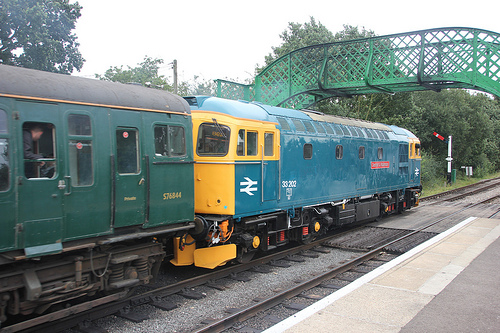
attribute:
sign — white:
[428, 130, 449, 144]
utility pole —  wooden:
[162, 52, 189, 94]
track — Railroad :
[5, 184, 499, 329]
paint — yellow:
[209, 163, 231, 200]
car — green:
[5, 65, 199, 288]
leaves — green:
[0, 0, 85, 75]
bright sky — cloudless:
[61, 0, 498, 93]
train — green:
[58, 82, 189, 271]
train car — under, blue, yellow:
[166, 93, 426, 273]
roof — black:
[1, 61, 192, 115]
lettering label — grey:
[364, 153, 404, 179]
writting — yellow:
[158, 188, 185, 203]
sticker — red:
[120, 128, 130, 140]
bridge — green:
[212, 25, 499, 110]